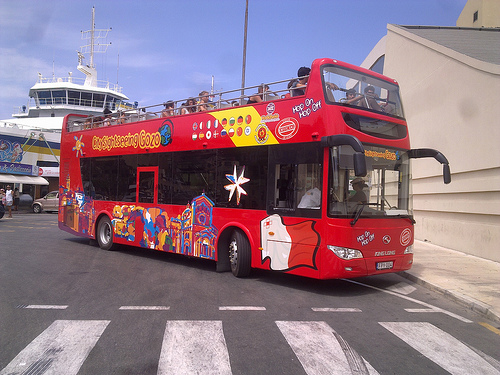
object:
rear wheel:
[97, 215, 119, 250]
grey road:
[0, 212, 500, 373]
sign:
[359, 119, 398, 138]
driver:
[349, 178, 366, 202]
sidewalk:
[399, 238, 500, 335]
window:
[158, 150, 213, 203]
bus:
[59, 58, 452, 280]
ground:
[406, 125, 461, 169]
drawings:
[111, 193, 218, 260]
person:
[6, 185, 15, 219]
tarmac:
[8, 248, 164, 300]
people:
[82, 65, 381, 127]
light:
[327, 244, 364, 260]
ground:
[365, 130, 411, 193]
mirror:
[78, 64, 410, 217]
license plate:
[375, 260, 394, 270]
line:
[154, 320, 232, 375]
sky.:
[0, 0, 462, 115]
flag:
[260, 213, 321, 271]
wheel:
[223, 228, 254, 277]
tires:
[95, 214, 251, 278]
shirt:
[6, 190, 13, 201]